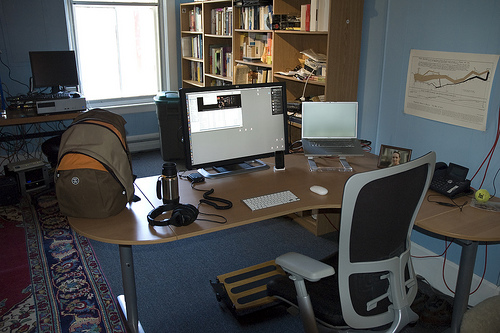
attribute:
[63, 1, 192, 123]
frame — wjote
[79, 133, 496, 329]
desk — wooden, l shaped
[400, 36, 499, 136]
chart — white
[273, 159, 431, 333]
office chair — black, gray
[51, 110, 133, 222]
backpack — brown, orange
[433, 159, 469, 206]
office phone — black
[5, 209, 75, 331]
carpet — red, blue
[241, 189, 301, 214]
keyboard — small, white, wireless, cordless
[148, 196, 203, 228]
headphones — black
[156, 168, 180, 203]
thermos — silver, metal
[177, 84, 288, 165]
computer screen — large, turned on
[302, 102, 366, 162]
laptop — silver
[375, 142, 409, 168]
picture — framed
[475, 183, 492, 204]
tennis ball — yellow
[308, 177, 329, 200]
mouse — white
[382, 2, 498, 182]
wall — blue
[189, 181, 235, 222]
wires — black